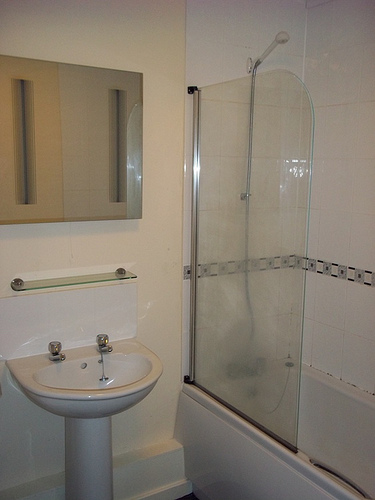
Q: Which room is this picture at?
A: It is at the bathroom.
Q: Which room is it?
A: It is a bathroom.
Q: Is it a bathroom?
A: Yes, it is a bathroom.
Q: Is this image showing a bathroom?
A: Yes, it is showing a bathroom.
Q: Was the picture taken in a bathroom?
A: Yes, it was taken in a bathroom.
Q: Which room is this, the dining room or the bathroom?
A: It is the bathroom.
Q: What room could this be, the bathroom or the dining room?
A: It is the bathroom.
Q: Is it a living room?
A: No, it is a bathroom.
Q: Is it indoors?
A: Yes, it is indoors.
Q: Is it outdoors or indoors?
A: It is indoors.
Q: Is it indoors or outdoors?
A: It is indoors.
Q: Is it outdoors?
A: No, it is indoors.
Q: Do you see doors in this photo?
A: Yes, there is a door.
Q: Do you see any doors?
A: Yes, there is a door.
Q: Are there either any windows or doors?
A: Yes, there is a door.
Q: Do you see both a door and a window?
A: No, there is a door but no windows.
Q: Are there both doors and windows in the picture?
A: No, there is a door but no windows.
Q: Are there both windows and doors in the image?
A: No, there is a door but no windows.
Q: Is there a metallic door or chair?
A: Yes, there is a metal door.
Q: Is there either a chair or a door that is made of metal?
A: Yes, the door is made of metal.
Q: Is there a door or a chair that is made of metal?
A: Yes, the door is made of metal.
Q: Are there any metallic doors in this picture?
A: Yes, there is a metal door.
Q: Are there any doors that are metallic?
A: Yes, there is a door that is metallic.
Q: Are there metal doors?
A: Yes, there is a door that is made of metal.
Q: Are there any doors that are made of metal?
A: Yes, there is a door that is made of metal.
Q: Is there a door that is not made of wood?
A: Yes, there is a door that is made of metal.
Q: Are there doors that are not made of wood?
A: Yes, there is a door that is made of metal.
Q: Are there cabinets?
A: No, there are no cabinets.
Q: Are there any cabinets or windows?
A: No, there are no cabinets or windows.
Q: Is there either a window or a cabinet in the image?
A: No, there are no cabinets or windows.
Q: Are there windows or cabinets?
A: No, there are no cabinets or windows.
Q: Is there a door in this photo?
A: Yes, there is a door.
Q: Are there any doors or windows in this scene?
A: Yes, there is a door.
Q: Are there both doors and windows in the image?
A: No, there is a door but no windows.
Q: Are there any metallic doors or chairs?
A: Yes, there is a metal door.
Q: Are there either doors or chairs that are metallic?
A: Yes, the door is metallic.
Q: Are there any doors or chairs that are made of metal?
A: Yes, the door is made of metal.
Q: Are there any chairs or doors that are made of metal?
A: Yes, the door is made of metal.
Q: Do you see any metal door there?
A: Yes, there is a metal door.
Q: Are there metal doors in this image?
A: Yes, there is a metal door.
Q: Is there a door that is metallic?
A: Yes, there is a door that is metallic.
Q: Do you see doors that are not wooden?
A: Yes, there is a metallic door.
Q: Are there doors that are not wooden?
A: Yes, there is a metallic door.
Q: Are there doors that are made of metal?
A: Yes, there is a door that is made of metal.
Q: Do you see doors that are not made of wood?
A: Yes, there is a door that is made of metal.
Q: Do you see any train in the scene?
A: No, there are no trains.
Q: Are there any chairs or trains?
A: No, there are no trains or chairs.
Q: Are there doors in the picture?
A: Yes, there is a door.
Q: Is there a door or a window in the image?
A: Yes, there is a door.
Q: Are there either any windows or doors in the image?
A: Yes, there is a door.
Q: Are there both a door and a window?
A: No, there is a door but no windows.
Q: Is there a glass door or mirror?
A: Yes, there is a glass door.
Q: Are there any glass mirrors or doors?
A: Yes, there is a glass door.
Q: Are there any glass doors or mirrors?
A: Yes, there is a glass door.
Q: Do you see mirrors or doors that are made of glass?
A: Yes, the door is made of glass.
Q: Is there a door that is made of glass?
A: Yes, there is a door that is made of glass.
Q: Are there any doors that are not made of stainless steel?
A: Yes, there is a door that is made of glass.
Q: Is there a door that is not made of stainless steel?
A: Yes, there is a door that is made of glass.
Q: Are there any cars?
A: No, there are no cars.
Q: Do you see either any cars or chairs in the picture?
A: No, there are no cars or chairs.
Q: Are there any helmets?
A: No, there are no helmets.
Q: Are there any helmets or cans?
A: No, there are no helmets or cans.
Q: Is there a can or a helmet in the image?
A: No, there are no helmets or cans.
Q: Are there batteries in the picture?
A: No, there are no batteries.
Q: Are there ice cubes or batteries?
A: No, there are no batteries or ice cubes.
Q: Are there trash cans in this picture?
A: No, there are no trash cans.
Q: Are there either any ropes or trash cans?
A: No, there are no trash cans or ropes.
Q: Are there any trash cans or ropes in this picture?
A: No, there are no trash cans or ropes.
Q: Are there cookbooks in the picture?
A: No, there are no cookbooks.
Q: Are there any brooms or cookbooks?
A: No, there are no cookbooks or brooms.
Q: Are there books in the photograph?
A: No, there are no books.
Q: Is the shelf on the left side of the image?
A: Yes, the shelf is on the left of the image.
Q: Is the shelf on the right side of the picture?
A: No, the shelf is on the left of the image.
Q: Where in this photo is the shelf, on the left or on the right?
A: The shelf is on the left of the image.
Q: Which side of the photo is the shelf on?
A: The shelf is on the left of the image.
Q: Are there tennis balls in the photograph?
A: No, there are no tennis balls.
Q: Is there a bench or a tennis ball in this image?
A: No, there are no tennis balls or benches.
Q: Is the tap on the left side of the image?
A: Yes, the tap is on the left of the image.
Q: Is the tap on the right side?
A: No, the tap is on the left of the image.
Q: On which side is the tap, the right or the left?
A: The tap is on the left of the image.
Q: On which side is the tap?
A: The tap is on the left of the image.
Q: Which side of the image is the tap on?
A: The tap is on the left of the image.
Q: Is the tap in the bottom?
A: Yes, the tap is in the bottom of the image.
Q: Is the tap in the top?
A: No, the tap is in the bottom of the image.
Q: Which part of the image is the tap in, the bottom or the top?
A: The tap is in the bottom of the image.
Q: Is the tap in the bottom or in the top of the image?
A: The tap is in the bottom of the image.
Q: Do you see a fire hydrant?
A: No, there are no fire hydrants.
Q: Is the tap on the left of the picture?
A: Yes, the tap is on the left of the image.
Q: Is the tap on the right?
A: No, the tap is on the left of the image.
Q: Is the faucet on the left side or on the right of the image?
A: The faucet is on the left of the image.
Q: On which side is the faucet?
A: The faucet is on the left of the image.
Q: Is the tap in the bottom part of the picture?
A: Yes, the tap is in the bottom of the image.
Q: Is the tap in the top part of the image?
A: No, the tap is in the bottom of the image.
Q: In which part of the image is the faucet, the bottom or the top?
A: The faucet is in the bottom of the image.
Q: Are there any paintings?
A: No, there are no paintings.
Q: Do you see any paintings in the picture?
A: No, there are no paintings.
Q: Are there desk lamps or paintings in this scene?
A: No, there are no paintings or desk lamps.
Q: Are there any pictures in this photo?
A: No, there are no pictures.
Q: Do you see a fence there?
A: No, there are no fences.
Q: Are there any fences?
A: No, there are no fences.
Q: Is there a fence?
A: No, there are no fences.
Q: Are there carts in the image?
A: No, there are no carts.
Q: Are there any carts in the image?
A: No, there are no carts.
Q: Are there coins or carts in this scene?
A: No, there are no carts or coins.